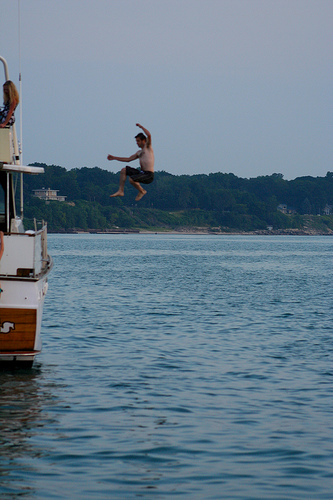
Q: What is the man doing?
A: Jumping.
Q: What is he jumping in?
A: Water.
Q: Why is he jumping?
A: Fun.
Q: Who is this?
A: Man.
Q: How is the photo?
A: Clear.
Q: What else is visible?
A: Boat.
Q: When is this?
A: Daytime.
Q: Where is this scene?
A: At a lake.